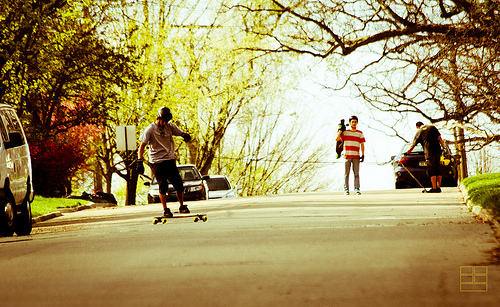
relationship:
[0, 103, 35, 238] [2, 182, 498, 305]
car parked in street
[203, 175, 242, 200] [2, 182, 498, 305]
car parked in street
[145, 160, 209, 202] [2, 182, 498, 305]
car parked in street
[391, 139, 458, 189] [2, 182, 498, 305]
car parked in street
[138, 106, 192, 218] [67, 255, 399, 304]
man skating in road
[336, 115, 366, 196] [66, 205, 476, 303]
man standing in street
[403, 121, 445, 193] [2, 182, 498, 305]
man standing in street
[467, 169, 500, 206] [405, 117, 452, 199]
grass by skater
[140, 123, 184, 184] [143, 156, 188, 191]
skater has shorts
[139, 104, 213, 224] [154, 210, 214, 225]
man riding skateboard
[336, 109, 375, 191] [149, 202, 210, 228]
man holding skateboard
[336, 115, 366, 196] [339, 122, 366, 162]
man wearing shirt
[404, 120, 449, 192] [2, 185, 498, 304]
man standing on road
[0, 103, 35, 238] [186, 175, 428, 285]
car parked on road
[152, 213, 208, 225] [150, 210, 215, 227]
skateboard on skateboard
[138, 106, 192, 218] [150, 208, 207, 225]
man on skateboard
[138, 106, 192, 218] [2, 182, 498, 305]
man in street